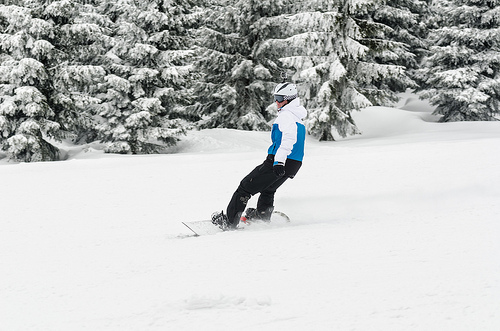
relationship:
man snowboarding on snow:
[212, 80, 308, 228] [2, 119, 496, 329]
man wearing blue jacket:
[212, 80, 308, 228] [254, 95, 316, 163]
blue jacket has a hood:
[254, 95, 316, 163] [275, 92, 319, 122]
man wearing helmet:
[212, 80, 308, 228] [274, 83, 298, 101]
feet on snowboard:
[204, 206, 276, 227] [182, 208, 290, 240]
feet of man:
[204, 206, 276, 227] [212, 80, 308, 228]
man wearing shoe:
[212, 80, 308, 228] [210, 212, 235, 229]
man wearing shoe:
[212, 80, 308, 228] [247, 205, 272, 222]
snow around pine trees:
[343, 105, 498, 147] [350, 0, 457, 120]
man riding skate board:
[212, 80, 308, 228] [186, 201, 290, 237]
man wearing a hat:
[212, 80, 308, 228] [269, 78, 300, 105]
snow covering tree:
[425, 21, 495, 91] [398, 0, 498, 125]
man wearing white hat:
[212, 80, 308, 228] [268, 73, 298, 96]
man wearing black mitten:
[212, 80, 308, 228] [270, 162, 286, 179]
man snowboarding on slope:
[212, 80, 308, 228] [0, 136, 498, 329]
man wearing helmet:
[212, 80, 308, 228] [268, 80, 300, 97]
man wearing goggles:
[212, 80, 308, 228] [272, 93, 295, 102]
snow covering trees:
[287, 15, 411, 93] [320, 15, 456, 78]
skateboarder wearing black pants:
[213, 76, 310, 230] [227, 160, 289, 223]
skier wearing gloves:
[182, 77, 309, 233] [269, 166, 284, 178]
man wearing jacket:
[212, 80, 308, 228] [256, 99, 312, 166]